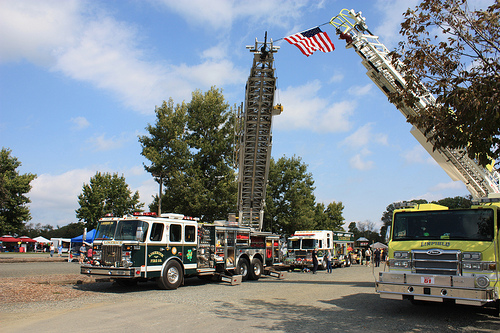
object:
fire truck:
[81, 29, 279, 291]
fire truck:
[329, 8, 500, 312]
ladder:
[236, 32, 283, 231]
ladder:
[330, 6, 500, 203]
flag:
[285, 25, 335, 57]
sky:
[1, 0, 500, 224]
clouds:
[0, 0, 133, 64]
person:
[312, 247, 318, 274]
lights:
[133, 212, 157, 216]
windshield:
[95, 219, 146, 240]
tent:
[70, 229, 111, 262]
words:
[149, 258, 163, 263]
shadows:
[216, 298, 500, 331]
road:
[1, 260, 498, 332]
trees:
[76, 170, 142, 234]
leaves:
[398, 16, 412, 35]